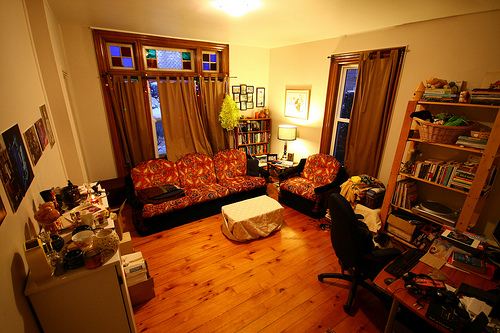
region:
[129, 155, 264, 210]
The colorful sofa in the center of the room.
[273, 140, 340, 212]
The small colorful one seater chair.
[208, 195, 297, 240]
The center table.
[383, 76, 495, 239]
The wooden book shelf on the right.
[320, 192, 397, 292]
The black computer chair.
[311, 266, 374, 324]
The feet of the black computer chair.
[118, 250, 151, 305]
The box on the floor on the left.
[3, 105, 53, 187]
The frames on the left wall.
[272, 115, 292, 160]
The small lamp in the corner.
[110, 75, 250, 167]
The brown curtains on the center window.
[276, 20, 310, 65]
the wall is white in color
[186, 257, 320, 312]
this is the floor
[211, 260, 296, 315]
the floor is made of wood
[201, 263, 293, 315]
the wood is brown in color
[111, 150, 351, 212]
this is a chair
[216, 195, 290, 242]
this is a table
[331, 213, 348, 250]
the chair is black in color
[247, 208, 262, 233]
the cloth is white in color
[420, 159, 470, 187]
these are several books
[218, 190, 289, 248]
Small covered table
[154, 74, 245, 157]
Brown drapes hanging in the window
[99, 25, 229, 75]
Stained glass windows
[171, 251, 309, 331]
Natural wood flooring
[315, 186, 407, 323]
Swivel chair on wheels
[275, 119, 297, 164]
Small lamp sitting on a table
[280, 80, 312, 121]
Picture hanging on the wall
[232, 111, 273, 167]
Small bookcase in the corner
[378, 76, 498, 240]
Cluttered set of shelves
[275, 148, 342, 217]
Chair in a living room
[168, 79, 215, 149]
this is a curtain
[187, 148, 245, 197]
this is a sofa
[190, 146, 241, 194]
the sofa is red in color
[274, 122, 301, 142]
this is a lampstand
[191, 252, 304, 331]
the floor is wooden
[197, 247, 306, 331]
the floor is brown in color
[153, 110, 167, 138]
the window is open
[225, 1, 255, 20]
the light is on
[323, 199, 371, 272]
the chair is black in color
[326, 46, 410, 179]
Brown curtain half open.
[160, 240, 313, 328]
Wooden floor.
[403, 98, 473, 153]
Basket on bookshelf.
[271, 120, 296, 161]
Table lamp turned on.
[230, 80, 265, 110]
Cluster of pictures on wall.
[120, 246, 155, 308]
Box filled with papers.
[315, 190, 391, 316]
Black desk chair.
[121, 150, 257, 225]
Couch with three cushions.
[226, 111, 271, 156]
Book case against wall.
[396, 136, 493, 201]
Books sitting horizontal and vertically on bookshelf.